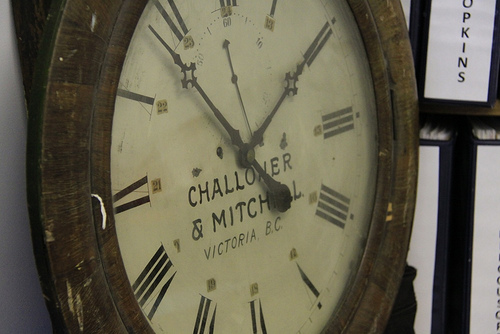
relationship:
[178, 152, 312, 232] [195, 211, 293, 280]
clock maker and location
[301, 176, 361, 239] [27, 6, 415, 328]
number on clock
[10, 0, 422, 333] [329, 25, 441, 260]
clock with frame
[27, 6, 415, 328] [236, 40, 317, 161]
clock with hand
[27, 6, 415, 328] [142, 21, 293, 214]
clock with minute hand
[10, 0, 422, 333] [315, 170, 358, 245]
clock with roman numerals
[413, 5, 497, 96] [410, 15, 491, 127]
paper on side binder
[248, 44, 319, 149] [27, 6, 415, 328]
hand of clock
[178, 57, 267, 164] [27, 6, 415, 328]
minute hand of clock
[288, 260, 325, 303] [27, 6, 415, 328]
number on clock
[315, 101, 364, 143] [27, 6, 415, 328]
number on clock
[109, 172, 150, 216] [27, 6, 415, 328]
number on clock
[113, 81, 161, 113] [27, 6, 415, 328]
number on clock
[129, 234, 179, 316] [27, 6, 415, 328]
number on clock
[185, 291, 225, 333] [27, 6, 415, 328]
number on clock